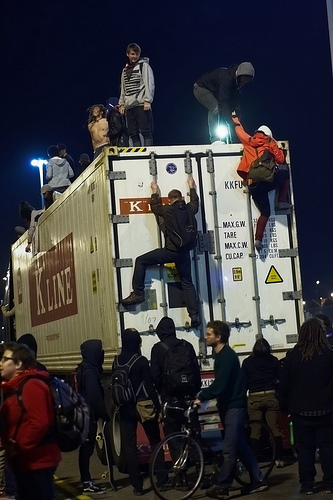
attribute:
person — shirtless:
[85, 101, 108, 161]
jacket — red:
[1, 367, 64, 472]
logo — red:
[29, 231, 81, 327]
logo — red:
[118, 196, 186, 217]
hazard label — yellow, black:
[264, 264, 283, 285]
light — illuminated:
[28, 157, 50, 170]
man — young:
[229, 112, 293, 252]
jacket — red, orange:
[229, 112, 286, 177]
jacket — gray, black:
[195, 65, 235, 125]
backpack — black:
[162, 199, 204, 250]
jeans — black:
[214, 409, 263, 486]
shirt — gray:
[118, 63, 154, 101]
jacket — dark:
[76, 338, 110, 424]